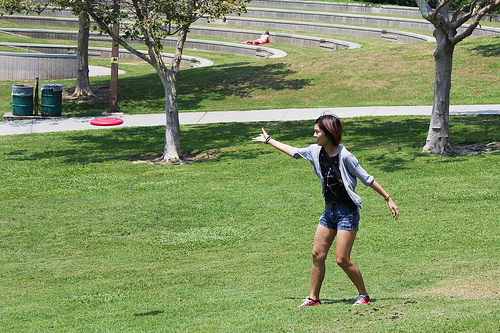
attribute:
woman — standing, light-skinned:
[253, 115, 401, 307]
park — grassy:
[0, 1, 497, 332]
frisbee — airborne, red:
[90, 117, 123, 125]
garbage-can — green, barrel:
[11, 85, 35, 118]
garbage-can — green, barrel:
[42, 83, 63, 118]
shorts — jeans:
[319, 199, 359, 231]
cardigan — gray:
[292, 144, 374, 208]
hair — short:
[318, 115, 343, 145]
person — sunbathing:
[246, 32, 271, 46]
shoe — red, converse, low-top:
[299, 297, 322, 307]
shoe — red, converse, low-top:
[353, 295, 369, 306]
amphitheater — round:
[2, 1, 498, 82]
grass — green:
[2, 115, 498, 331]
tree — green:
[67, 1, 249, 163]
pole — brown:
[109, 0, 119, 112]